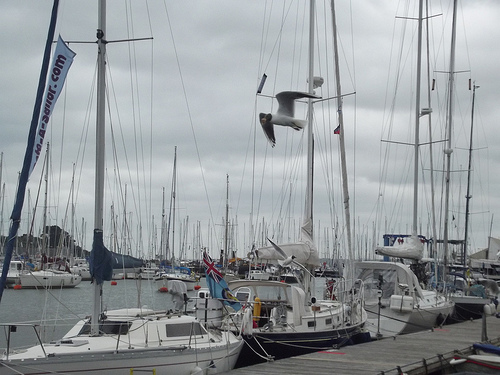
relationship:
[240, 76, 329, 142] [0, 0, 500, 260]
bird in gray sky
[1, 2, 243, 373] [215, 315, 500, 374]
boat in dock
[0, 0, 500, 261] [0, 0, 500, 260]
clouds in gray sky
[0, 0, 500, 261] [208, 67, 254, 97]
clouds in blue sky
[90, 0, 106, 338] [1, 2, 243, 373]
mast on boat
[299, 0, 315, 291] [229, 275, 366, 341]
mast on boat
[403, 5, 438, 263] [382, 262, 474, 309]
mast on boat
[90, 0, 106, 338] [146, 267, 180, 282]
mast on boat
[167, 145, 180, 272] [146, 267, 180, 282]
mast on boat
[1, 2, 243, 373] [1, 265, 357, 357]
boat in water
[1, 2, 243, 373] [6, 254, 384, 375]
boat in water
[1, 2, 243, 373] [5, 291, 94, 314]
boat in water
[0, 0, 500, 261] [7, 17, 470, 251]
clouds in sky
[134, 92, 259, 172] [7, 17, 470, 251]
clouds in sky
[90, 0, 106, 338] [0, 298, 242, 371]
mast on boat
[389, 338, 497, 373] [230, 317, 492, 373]
fence on boardwalk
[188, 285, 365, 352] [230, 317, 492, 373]
boat near boardwalk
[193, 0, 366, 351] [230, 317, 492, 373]
boat near boardwalk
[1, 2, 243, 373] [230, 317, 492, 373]
boat near boardwalk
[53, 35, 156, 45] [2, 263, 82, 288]
crosspiece on boat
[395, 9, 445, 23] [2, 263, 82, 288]
crosspiece on boat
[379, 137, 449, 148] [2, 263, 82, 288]
crosspiece on boat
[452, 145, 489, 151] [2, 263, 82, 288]
crosspiece on boat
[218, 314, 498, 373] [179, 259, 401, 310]
boardwalk near boats